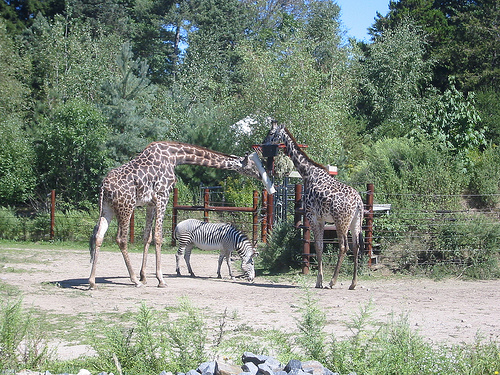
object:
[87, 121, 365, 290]
animals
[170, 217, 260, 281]
zebra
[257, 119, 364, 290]
giraffes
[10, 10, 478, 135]
trees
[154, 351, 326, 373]
rocks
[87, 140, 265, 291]
giraffes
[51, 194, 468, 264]
fence